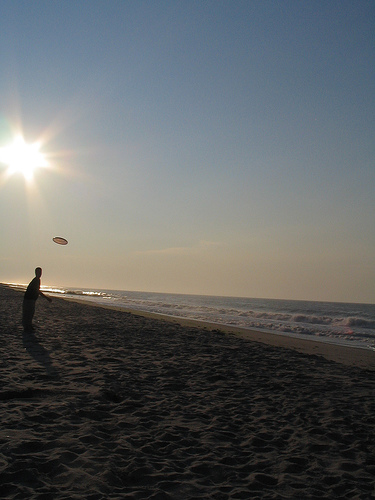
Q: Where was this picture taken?
A: A beach.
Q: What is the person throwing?
A: A Frisbee.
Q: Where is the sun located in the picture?
A: Left side above the person.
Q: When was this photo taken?
A: During daylight.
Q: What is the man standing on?
A: Sand.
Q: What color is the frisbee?
A: White.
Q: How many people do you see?
A: 1.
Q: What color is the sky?
A: Blue.